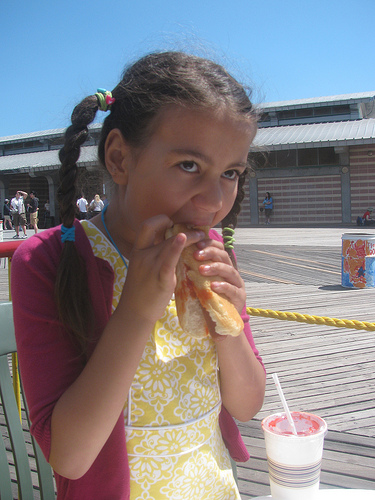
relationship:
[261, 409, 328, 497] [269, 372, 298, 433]
drink has straw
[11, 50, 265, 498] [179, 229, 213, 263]
girl eating bun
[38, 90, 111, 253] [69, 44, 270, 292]
pigtail on girl